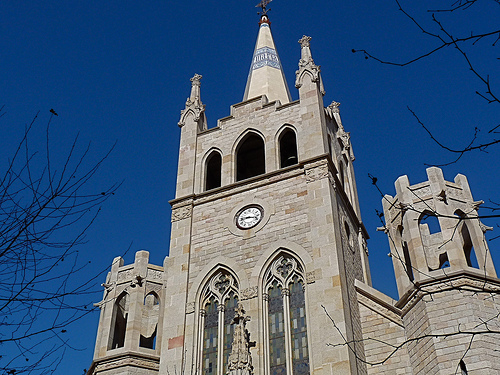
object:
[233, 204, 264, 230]
clock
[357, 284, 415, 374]
wall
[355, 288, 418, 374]
wall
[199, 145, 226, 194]
windows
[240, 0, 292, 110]
spire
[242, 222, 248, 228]
number marks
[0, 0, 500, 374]
blue sky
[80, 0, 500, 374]
stone church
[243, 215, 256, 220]
black hands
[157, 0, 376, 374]
tower